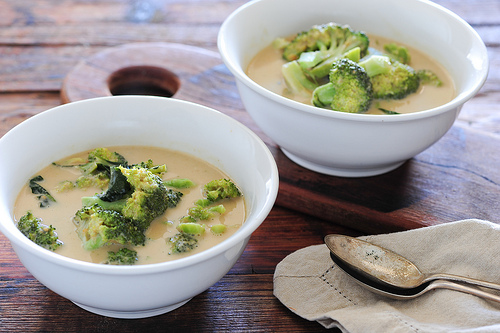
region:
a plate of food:
[6, 92, 279, 307]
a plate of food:
[228, 6, 482, 167]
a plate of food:
[210, 3, 497, 161]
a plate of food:
[8, 94, 288, 322]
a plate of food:
[14, 92, 282, 319]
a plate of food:
[19, 96, 288, 317]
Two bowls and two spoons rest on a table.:
[1, 0, 496, 329]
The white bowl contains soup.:
[3, 91, 279, 320]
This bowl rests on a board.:
[57, 2, 498, 252]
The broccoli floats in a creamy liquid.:
[15, 143, 247, 265]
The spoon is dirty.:
[322, 233, 498, 290]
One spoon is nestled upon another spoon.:
[322, 233, 498, 309]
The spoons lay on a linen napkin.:
[268, 214, 497, 329]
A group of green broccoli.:
[274, 22, 424, 112]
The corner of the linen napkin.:
[272, 245, 342, 321]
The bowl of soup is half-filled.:
[214, 2, 490, 179]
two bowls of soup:
[7, 2, 487, 312]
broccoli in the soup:
[5, 12, 465, 327]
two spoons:
[316, 205, 494, 308]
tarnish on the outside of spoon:
[325, 225, 498, 292]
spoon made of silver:
[326, 227, 486, 289]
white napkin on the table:
[251, 215, 496, 326]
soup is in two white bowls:
[12, 10, 474, 315]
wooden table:
[12, 10, 482, 312]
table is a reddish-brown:
[10, 0, 490, 320]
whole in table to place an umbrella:
[104, 61, 177, 98]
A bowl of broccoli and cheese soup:
[2, 73, 322, 323]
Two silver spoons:
[303, 223, 498, 326]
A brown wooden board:
[326, 174, 493, 217]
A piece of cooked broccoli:
[305, 59, 379, 110]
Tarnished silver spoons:
[315, 225, 498, 312]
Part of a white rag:
[415, 218, 497, 260]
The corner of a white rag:
[262, 247, 341, 319]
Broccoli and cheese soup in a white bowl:
[215, 5, 498, 179]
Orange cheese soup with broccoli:
[46, 153, 196, 252]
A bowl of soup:
[40, 92, 245, 320]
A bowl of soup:
[224, 26, 488, 159]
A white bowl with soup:
[15, 119, 266, 319]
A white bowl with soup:
[226, 17, 476, 184]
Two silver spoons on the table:
[322, 224, 497, 304]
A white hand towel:
[390, 208, 497, 252]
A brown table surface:
[209, 274, 282, 326]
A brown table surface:
[445, 138, 493, 205]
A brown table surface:
[11, 17, 178, 69]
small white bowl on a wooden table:
[1, 92, 283, 321]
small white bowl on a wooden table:
[215, 1, 490, 183]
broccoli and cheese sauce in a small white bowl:
[13, 144, 245, 264]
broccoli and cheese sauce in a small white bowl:
[245, 21, 456, 114]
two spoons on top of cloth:
[301, 222, 494, 317]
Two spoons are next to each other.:
[315, 233, 497, 314]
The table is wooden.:
[214, 296, 271, 331]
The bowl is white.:
[2, 105, 263, 312]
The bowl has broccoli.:
[87, 168, 154, 230]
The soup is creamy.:
[60, 223, 92, 256]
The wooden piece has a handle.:
[100, 46, 185, 98]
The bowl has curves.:
[295, 126, 395, 163]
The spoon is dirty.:
[326, 218, 412, 288]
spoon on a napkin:
[326, 225, 499, 304]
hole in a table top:
[97, 56, 184, 106]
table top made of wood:
[3, 1, 499, 331]